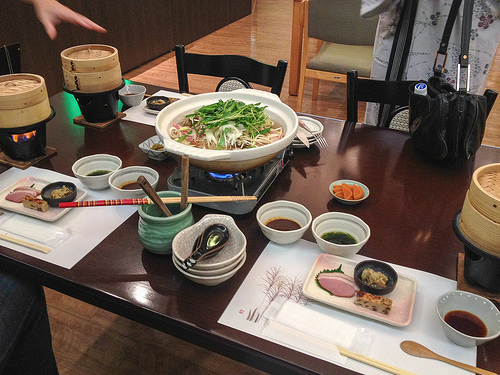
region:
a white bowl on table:
[428, 278, 498, 353]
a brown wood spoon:
[390, 333, 495, 372]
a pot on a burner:
[145, 82, 300, 204]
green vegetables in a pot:
[171, 95, 275, 150]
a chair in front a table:
[168, 39, 293, 102]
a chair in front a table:
[339, 58, 499, 140]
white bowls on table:
[168, 213, 249, 290]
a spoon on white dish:
[174, 218, 232, 277]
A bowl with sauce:
[265, 205, 300, 225]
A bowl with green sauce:
[323, 217, 358, 237]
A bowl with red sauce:
[265, 206, 300, 227]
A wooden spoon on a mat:
[406, 342, 418, 352]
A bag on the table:
[422, 102, 471, 152]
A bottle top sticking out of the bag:
[416, 85, 424, 92]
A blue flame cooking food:
[211, 174, 226, 176]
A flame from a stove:
[13, 135, 18, 141]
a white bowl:
[298, 213, 311, 229]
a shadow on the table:
[120, 257, 152, 287]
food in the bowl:
[190, 105, 275, 140]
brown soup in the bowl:
[450, 304, 475, 331]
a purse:
[412, 96, 479, 158]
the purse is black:
[415, 104, 473, 162]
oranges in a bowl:
[334, 183, 361, 200]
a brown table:
[379, 207, 440, 246]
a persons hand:
[39, 9, 106, 37]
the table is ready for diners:
[2, 35, 499, 369]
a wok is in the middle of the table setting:
[152, 88, 298, 174]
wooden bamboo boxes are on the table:
[0, 40, 122, 160]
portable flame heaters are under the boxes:
[0, 85, 126, 167]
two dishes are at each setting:
[69, 143, 161, 208]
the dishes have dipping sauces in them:
[71, 150, 162, 203]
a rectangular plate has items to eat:
[3, 173, 85, 222]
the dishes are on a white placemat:
[218, 237, 480, 374]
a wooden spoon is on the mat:
[396, 333, 490, 373]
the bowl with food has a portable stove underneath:
[154, 85, 301, 217]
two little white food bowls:
[254, 198, 372, 255]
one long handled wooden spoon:
[395, 340, 496, 374]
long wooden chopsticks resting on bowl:
[47, 192, 259, 209]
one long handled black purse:
[414, 6, 491, 167]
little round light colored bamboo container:
[56, 40, 126, 95]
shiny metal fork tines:
[316, 134, 328, 151]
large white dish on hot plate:
[152, 82, 291, 214]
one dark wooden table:
[2, 27, 499, 369]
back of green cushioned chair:
[296, 0, 378, 88]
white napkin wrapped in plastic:
[261, 293, 381, 358]